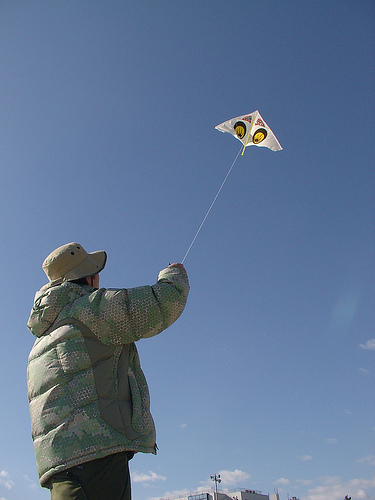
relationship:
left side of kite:
[213, 109, 257, 148] [212, 107, 283, 158]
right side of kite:
[247, 109, 283, 151] [212, 107, 283, 158]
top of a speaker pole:
[209, 470, 223, 483] [211, 471, 223, 499]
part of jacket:
[58, 318, 143, 440] [25, 262, 192, 490]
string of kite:
[176, 146, 243, 267] [212, 107, 283, 158]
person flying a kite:
[23, 239, 194, 500] [212, 107, 283, 158]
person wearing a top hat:
[23, 239, 194, 500] [40, 241, 109, 284]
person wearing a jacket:
[23, 239, 194, 500] [25, 262, 192, 490]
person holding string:
[23, 239, 194, 500] [176, 146, 243, 267]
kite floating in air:
[212, 107, 283, 158] [2, 1, 374, 500]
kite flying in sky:
[212, 107, 283, 158] [0, 0, 374, 499]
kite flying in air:
[212, 107, 283, 158] [2, 1, 374, 500]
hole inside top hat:
[68, 248, 77, 258] [40, 241, 109, 284]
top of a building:
[230, 490, 271, 500] [226, 487, 268, 499]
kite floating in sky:
[212, 107, 283, 158] [0, 0, 374, 499]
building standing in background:
[226, 487, 268, 499] [0, 1, 373, 499]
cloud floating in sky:
[128, 469, 168, 485] [0, 0, 374, 499]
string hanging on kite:
[176, 146, 243, 267] [212, 107, 283, 158]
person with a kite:
[23, 239, 194, 500] [212, 107, 283, 158]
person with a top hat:
[23, 239, 194, 500] [40, 241, 109, 284]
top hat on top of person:
[40, 241, 109, 284] [23, 239, 194, 500]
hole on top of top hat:
[74, 244, 83, 254] [40, 241, 109, 284]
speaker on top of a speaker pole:
[214, 473, 223, 481] [211, 471, 223, 499]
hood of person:
[29, 281, 83, 336] [23, 239, 194, 500]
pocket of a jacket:
[126, 368, 142, 426] [25, 262, 192, 490]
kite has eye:
[212, 107, 283, 158] [252, 124, 267, 144]